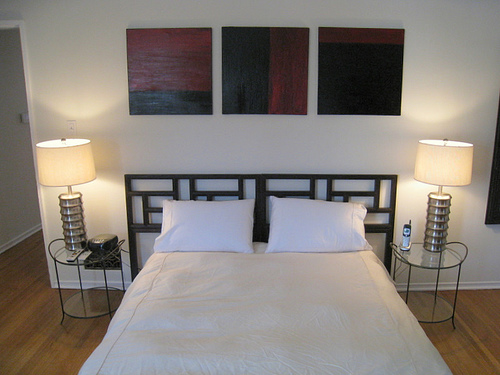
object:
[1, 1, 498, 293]
wall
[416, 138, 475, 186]
lamp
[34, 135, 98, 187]
lamp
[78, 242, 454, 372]
sheet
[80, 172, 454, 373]
bed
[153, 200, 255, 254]
pillow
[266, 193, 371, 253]
pillow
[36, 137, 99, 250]
lamp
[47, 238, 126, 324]
table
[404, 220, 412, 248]
phone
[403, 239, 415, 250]
stand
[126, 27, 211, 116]
picture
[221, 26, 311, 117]
picture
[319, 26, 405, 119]
picture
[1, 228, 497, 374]
floor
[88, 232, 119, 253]
clock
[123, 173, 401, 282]
headboard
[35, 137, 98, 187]
shade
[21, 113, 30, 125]
panel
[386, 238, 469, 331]
table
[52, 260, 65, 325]
legs